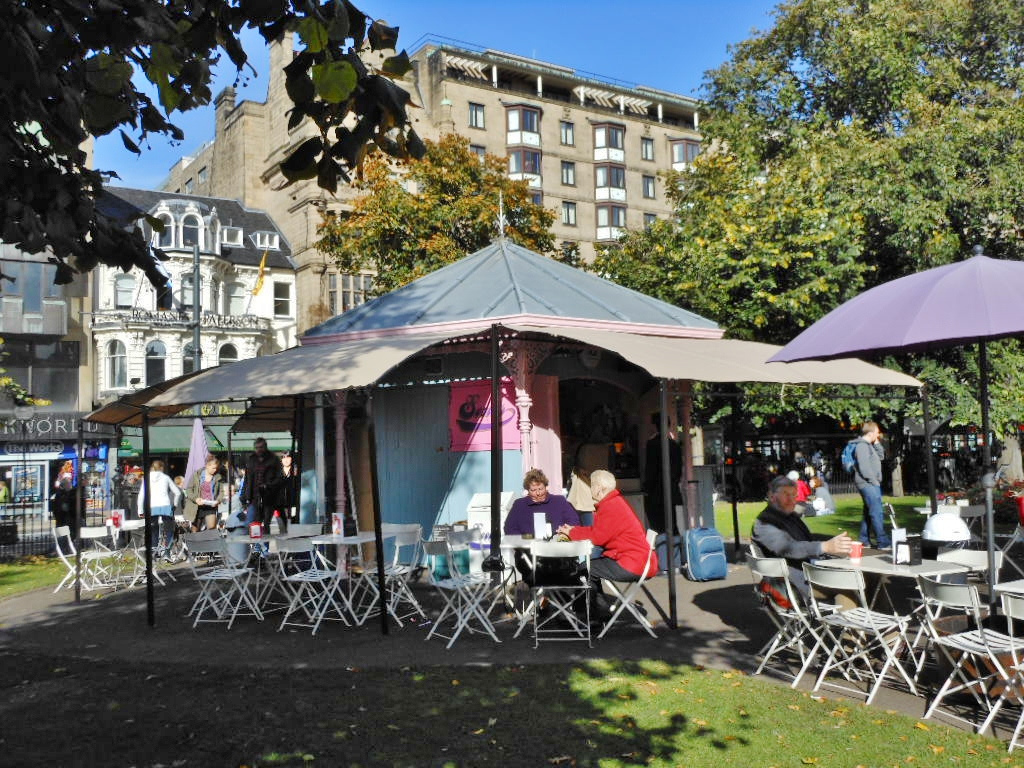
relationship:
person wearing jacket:
[504, 468, 582, 619] [500, 493, 583, 535]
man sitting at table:
[734, 467, 869, 681] [807, 547, 985, 710]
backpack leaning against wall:
[677, 525, 734, 588] [533, 372, 698, 576]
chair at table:
[516, 549, 601, 656] [464, 536, 637, 643]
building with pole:
[70, 215, 948, 650] [133, 420, 162, 622]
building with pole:
[70, 215, 948, 650] [360, 396, 404, 645]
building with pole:
[70, 215, 948, 650] [656, 383, 696, 647]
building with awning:
[70, 215, 948, 650] [116, 325, 467, 453]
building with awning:
[70, 215, 948, 650] [507, 309, 935, 405]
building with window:
[93, 186, 296, 520] [139, 329, 170, 394]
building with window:
[93, 186, 296, 520] [183, 340, 209, 390]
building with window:
[93, 186, 296, 520] [211, 340, 244, 371]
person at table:
[505, 465, 579, 552] [494, 530, 588, 578]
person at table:
[554, 461, 658, 636] [494, 530, 588, 578]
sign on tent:
[442, 368, 529, 461] [85, 180, 930, 628]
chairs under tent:
[85, 188, 954, 647] [172, 513, 430, 643]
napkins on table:
[881, 523, 908, 565] [818, 545, 981, 693]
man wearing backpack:
[833, 411, 903, 552] [837, 437, 866, 483]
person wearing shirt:
[504, 468, 582, 619] [502, 489, 583, 531]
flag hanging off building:
[245, 245, 284, 315] [90, 182, 302, 520]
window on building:
[585, 119, 637, 163] [161, 24, 751, 331]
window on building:
[267, 275, 294, 323] [90, 182, 302, 520]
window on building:
[505, 139, 523, 172] [140, 20, 774, 394]